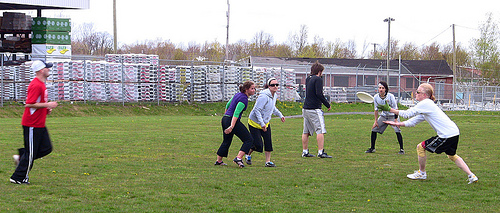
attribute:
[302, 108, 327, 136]
shorts — grey and white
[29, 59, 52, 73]
cap — white and black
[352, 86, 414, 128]
frisbee — white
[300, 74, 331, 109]
shirt — green, long sleeved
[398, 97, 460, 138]
shirt — white, long sleeved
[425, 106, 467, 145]
shirt — red, short sleevedd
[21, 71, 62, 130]
shirt — red, short sleeved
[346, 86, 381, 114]
frisbee — white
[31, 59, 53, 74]
cap — white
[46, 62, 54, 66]
bill — black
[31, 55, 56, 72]
cap — white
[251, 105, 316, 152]
ground — black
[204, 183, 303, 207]
grass — green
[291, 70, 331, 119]
shirt — dark, long sleeved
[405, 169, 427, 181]
shoe — white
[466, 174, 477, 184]
shoe — white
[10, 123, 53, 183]
pants — black, striped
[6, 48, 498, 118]
fence — grey, chain linked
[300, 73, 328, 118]
shirt — long sleeved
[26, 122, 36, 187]
stripe — white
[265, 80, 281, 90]
shades — dark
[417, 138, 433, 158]
patch — red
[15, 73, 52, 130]
shirt — red, short sleeved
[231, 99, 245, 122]
sleeve — long